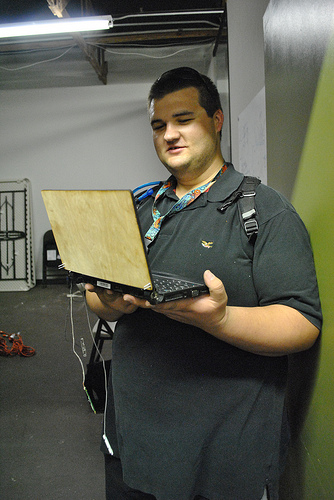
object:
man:
[83, 63, 325, 500]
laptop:
[39, 187, 211, 306]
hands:
[151, 269, 229, 330]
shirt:
[98, 160, 324, 500]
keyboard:
[149, 269, 207, 296]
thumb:
[203, 269, 228, 301]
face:
[148, 86, 215, 180]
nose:
[163, 122, 180, 142]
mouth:
[164, 145, 188, 152]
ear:
[213, 108, 225, 134]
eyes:
[154, 123, 166, 130]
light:
[0, 13, 114, 38]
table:
[0, 175, 37, 294]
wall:
[1, 91, 232, 280]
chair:
[42, 229, 75, 289]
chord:
[0, 328, 37, 358]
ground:
[0, 284, 116, 500]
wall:
[263, 0, 334, 500]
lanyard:
[144, 163, 230, 256]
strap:
[239, 174, 262, 247]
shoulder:
[225, 166, 309, 236]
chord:
[66, 276, 115, 466]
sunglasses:
[155, 66, 218, 110]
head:
[146, 65, 224, 183]